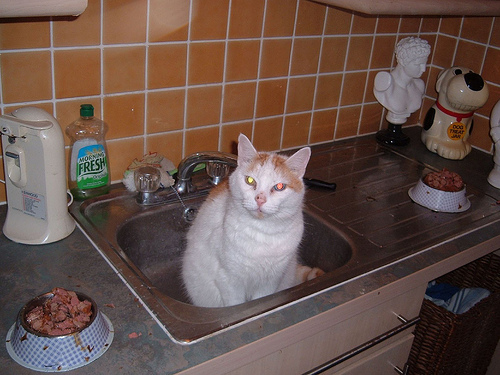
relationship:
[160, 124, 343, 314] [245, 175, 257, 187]
cat yellow eye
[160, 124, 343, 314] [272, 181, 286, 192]
cat red eye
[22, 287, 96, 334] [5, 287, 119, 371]
food in bowl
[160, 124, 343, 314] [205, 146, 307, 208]
cat brown spots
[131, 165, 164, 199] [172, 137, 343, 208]
knob on faucet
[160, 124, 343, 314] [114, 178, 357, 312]
cat in sink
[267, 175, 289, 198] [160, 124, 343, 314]
eye of cat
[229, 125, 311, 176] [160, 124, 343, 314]
ears of cat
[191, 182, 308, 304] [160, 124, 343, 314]
fur on cat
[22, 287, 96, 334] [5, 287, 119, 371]
food on bowl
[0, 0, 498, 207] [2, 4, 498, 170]
backsplash of backsplash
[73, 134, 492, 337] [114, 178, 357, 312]
stainless steel sink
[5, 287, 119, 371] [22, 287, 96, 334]
bowl of catfood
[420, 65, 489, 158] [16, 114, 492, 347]
dog on counter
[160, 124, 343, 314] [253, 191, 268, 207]
cat with nose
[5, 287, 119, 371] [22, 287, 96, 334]
bowl of food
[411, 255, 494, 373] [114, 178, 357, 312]
basket under sink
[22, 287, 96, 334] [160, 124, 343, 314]
food for cat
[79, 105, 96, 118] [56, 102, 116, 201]
cap of soap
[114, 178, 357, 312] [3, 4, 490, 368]
sink in kitchen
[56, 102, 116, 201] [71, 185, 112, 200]
bottle of liquid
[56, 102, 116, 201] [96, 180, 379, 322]
bottle behind sink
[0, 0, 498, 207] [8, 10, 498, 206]
backsplash on wall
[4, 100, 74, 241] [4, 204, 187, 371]
opener on counter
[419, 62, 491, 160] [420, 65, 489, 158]
jar shaped like dog